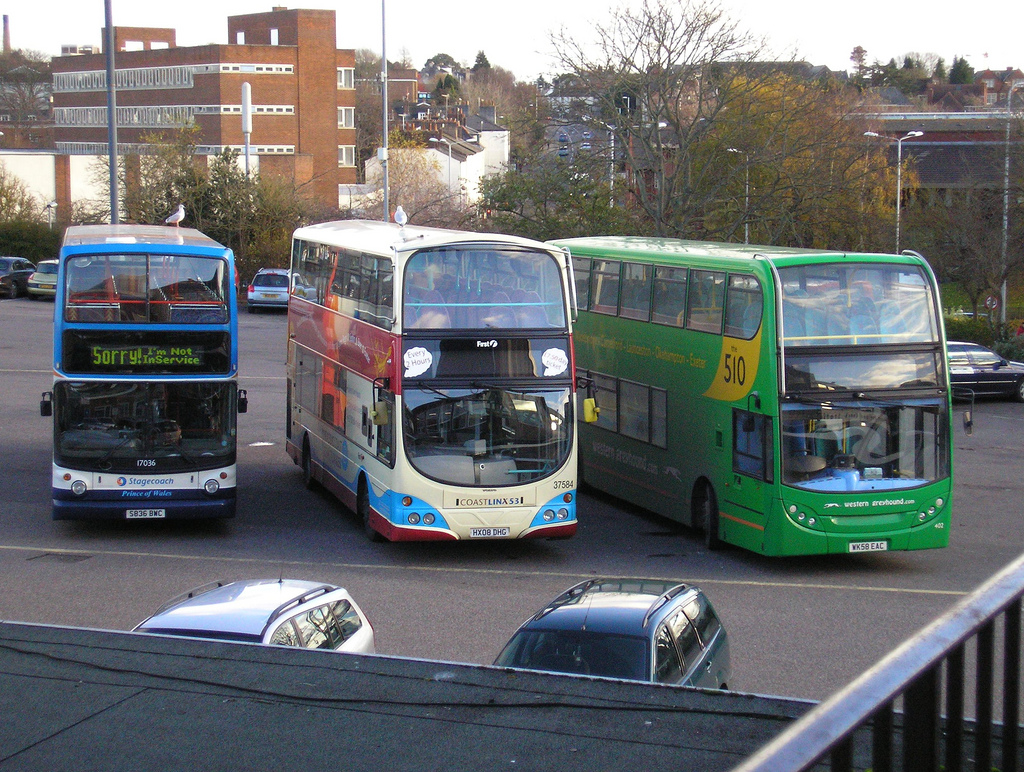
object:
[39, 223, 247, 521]
bus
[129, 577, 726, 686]
cars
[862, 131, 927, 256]
lights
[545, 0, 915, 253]
trees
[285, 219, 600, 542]
bus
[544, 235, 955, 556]
bus